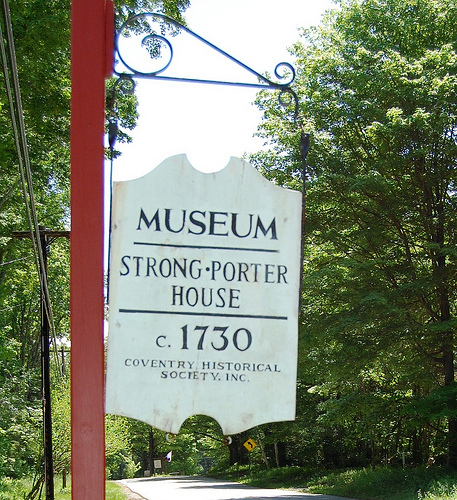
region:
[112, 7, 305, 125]
Wrought iron sign hanging post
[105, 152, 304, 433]
Wooden sign on support post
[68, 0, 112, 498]
Red painted wooden sign pole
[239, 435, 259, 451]
Yellow diamond road curve sign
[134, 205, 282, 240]
Museum painted on sign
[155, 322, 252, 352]
Building built year on sign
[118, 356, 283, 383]
Organization building owner identification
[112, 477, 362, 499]
Paved road through forest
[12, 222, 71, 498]
Wooden electric power utility pole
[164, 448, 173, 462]
Flag on pole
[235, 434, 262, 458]
yellow traffic sign on side of road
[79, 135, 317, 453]
white sign attached to red pole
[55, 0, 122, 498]
red metal support pole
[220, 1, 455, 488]
tall green trees on side of road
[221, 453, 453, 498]
patch of green grass on side of road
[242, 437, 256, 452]
black arrow on yellow sign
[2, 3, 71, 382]
power line in the sky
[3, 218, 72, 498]
wooden electric line support pole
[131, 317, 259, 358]
year on white sign in black print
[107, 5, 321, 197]
metal lines attaching white sign to red pole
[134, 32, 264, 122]
the sky between the trees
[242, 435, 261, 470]
a yellow street sign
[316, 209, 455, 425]
large trees off the road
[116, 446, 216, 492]
the street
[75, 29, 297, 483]
a large sign next to the road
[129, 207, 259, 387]
writing on the sign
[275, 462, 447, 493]
grass next to the street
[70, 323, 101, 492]
a red post holding the sign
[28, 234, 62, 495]
a telephone pole next to the road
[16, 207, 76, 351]
wires coming off the telephone pole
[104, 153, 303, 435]
A white sign hanging on pole.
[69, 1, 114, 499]
A painted red pole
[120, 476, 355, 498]
A paved road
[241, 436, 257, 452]
A yellow sign with arrow.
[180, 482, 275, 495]
A shadow on the ground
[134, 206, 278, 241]
Words saying "museum" on sign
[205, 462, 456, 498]
Grass near side of road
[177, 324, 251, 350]
Numbers saying "1730"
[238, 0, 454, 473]
A large tree on the side of road.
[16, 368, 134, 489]
A small tree on side of road.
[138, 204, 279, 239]
the word museum on a sign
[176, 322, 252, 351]
1730 on a sign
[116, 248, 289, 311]
strong porter house on a sign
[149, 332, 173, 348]
the letter c for circa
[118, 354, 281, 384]
coventry historical society, inc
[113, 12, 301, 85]
a black metal scroll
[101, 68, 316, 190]
black metal on a sign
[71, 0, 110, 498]
a red metal sign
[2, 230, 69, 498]
a black metal pole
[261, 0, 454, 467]
a clump of trees by the road